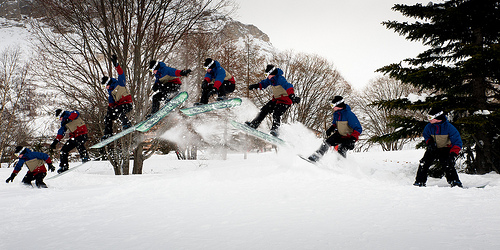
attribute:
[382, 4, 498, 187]
tree guy — pine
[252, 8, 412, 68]
sky — gray 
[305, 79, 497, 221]
snowboarder — Snowboarder's , white 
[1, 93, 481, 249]
hill — up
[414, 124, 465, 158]
jacket — man's, brown , blue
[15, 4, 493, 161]
sky — gray 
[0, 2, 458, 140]
sky — blue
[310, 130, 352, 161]
skipants — black 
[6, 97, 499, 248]
snow — spitting swirling white 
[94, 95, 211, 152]
snowboard — light green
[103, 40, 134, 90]
arm — raised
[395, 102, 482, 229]
hat — black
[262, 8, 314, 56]
clouds — white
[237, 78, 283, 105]
arm — raised